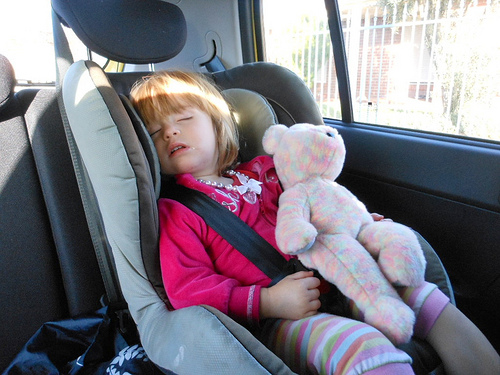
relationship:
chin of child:
[173, 153, 198, 168] [126, 66, 498, 375]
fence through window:
[279, 6, 498, 113] [256, 7, 499, 147]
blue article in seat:
[45, 322, 144, 366] [0, 58, 158, 372]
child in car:
[126, 66, 498, 375] [7, 6, 498, 374]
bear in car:
[261, 121, 456, 349] [7, 6, 498, 374]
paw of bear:
[282, 216, 319, 255] [259, 117, 427, 344]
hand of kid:
[263, 269, 321, 321] [77, 70, 401, 327]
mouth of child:
[166, 138, 190, 158] [126, 66, 498, 375]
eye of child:
[168, 108, 207, 131] [126, 66, 498, 375]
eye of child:
[175, 112, 195, 123] [126, 66, 498, 375]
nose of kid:
[157, 119, 182, 142] [141, 61, 438, 343]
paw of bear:
[378, 247, 427, 291] [259, 117, 427, 344]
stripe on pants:
[334, 350, 407, 364] [255, 285, 452, 373]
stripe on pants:
[291, 321, 308, 364] [255, 285, 452, 373]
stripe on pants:
[420, 282, 445, 347] [255, 285, 452, 373]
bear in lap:
[261, 121, 426, 349] [278, 245, 416, 353]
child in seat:
[126, 69, 494, 372] [49, 0, 458, 374]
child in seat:
[126, 66, 498, 375] [73, 54, 475, 374]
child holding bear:
[126, 66, 498, 375] [261, 121, 426, 349]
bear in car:
[261, 121, 426, 349] [7, 6, 498, 374]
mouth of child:
[166, 142, 190, 158] [126, 66, 498, 375]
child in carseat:
[126, 66, 498, 375] [81, 110, 174, 232]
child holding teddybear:
[126, 66, 498, 375] [254, 115, 451, 354]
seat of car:
[18, 12, 318, 372] [2, 6, 497, 326]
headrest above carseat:
[64, 1, 309, 146] [57, 13, 468, 369]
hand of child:
[263, 269, 322, 323] [126, 66, 498, 375]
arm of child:
[157, 196, 320, 322] [126, 66, 498, 375]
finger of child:
[301, 277, 320, 288] [126, 66, 498, 375]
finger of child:
[306, 289, 333, 298] [126, 66, 498, 375]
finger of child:
[309, 299, 319, 309] [126, 66, 498, 375]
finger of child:
[304, 309, 316, 316] [126, 66, 498, 375]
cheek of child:
[186, 130, 222, 160] [126, 66, 498, 375]